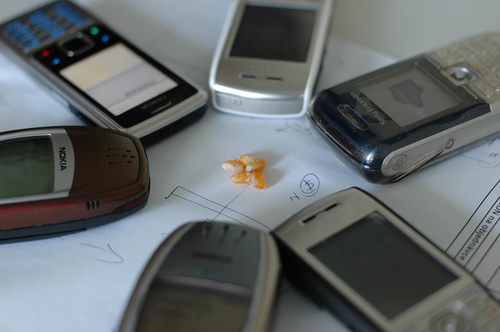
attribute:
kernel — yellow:
[251, 171, 265, 189]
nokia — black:
[58, 144, 68, 172]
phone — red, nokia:
[1, 125, 149, 240]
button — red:
[36, 46, 57, 58]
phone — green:
[275, 185, 497, 331]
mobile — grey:
[208, 4, 335, 119]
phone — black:
[1, 2, 207, 151]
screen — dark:
[226, 2, 318, 64]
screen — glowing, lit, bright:
[60, 42, 179, 118]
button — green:
[89, 25, 99, 38]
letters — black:
[191, 250, 235, 265]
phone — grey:
[309, 33, 496, 180]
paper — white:
[163, 122, 307, 156]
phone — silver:
[114, 219, 284, 331]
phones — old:
[6, 7, 495, 325]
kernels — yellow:
[221, 151, 268, 189]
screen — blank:
[308, 209, 459, 319]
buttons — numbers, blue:
[5, 2, 88, 46]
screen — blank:
[2, 134, 55, 200]